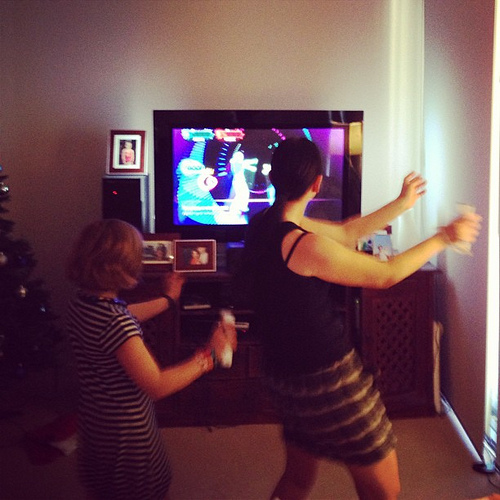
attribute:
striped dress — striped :
[57, 288, 172, 496]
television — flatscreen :
[147, 96, 372, 258]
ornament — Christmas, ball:
[16, 283, 28, 298]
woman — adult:
[220, 129, 469, 422]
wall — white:
[1, 1, 396, 333]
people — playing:
[64, 135, 482, 497]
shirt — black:
[240, 211, 358, 379]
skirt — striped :
[267, 349, 403, 465]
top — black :
[240, 204, 365, 373]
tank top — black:
[246, 210, 356, 370]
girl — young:
[39, 209, 269, 496]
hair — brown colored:
[63, 215, 153, 300]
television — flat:
[154, 108, 362, 243]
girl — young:
[69, 292, 185, 499]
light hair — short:
[67, 215, 147, 292]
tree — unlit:
[2, 168, 62, 416]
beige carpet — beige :
[1, 412, 489, 498]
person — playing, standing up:
[231, 133, 481, 498]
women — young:
[59, 150, 449, 468]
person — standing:
[234, 152, 391, 434]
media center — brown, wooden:
[92, 258, 454, 429]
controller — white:
[453, 203, 482, 260]